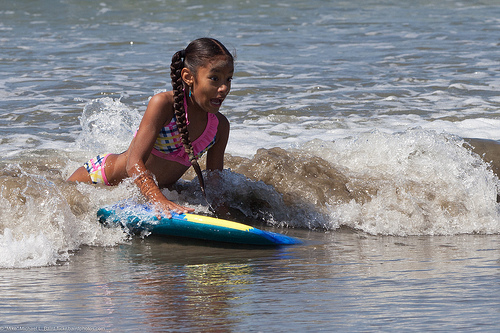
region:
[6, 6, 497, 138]
sea foam on water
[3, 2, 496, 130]
blue surface of water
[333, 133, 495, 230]
white water of crashed wave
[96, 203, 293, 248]
blue and yellow board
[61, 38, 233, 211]
girl on small surfboard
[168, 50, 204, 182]
hair in long braid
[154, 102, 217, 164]
top of pink bathing suit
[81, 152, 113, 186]
bottom of girl's bathing suit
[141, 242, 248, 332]
reflection of girl on water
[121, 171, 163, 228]
water splashing on arm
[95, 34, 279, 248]
girl is on surfboard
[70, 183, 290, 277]
blue and yellow surfboard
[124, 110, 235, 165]
girl has pink top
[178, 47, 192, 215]
girl has long hair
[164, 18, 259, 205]
girl has brown hair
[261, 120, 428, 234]
white and brown water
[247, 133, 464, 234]
wave is crashing on shore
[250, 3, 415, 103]
churning water behind girl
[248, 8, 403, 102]
water is light blue in distance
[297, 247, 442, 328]
shore is dark and wet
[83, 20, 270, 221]
small girl riding board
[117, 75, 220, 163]
pink bathing suit top on girl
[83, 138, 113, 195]
yellow and pink bottom on bathing suit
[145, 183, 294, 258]
blue and yellow board under girl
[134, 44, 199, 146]
long braided hair of girl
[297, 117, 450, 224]
white water on top of wave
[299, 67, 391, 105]
white foam in brown water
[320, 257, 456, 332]
smooth water in front of wave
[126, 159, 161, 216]
water splashing on girl's wrist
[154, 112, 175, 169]
blue and yellow stripes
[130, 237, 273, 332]
reflection of surfer in the water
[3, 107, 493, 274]
a wave rolling in mixed with sand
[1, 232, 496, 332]
shallow water closer to shore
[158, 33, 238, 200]
a long braid in girls hair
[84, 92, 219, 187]
a pink simsuit with yellow and blue lines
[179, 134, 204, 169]
a rubberband ties the braid end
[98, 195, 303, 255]
blue and yelloe surf board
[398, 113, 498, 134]
foamy water behind the wave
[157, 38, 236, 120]
a face with surprise and excitement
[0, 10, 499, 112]
ripples and waves catch the light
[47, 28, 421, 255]
a young girl playing at the beach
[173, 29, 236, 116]
the head of a girl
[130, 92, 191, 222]
the arm of a girl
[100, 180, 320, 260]
a yellow and blue float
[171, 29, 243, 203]
a girl with long hair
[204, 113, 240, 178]
the arm of a girl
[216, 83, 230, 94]
the nose of a girl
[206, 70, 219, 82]
the eye of a girl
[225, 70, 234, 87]
the eye of a girl